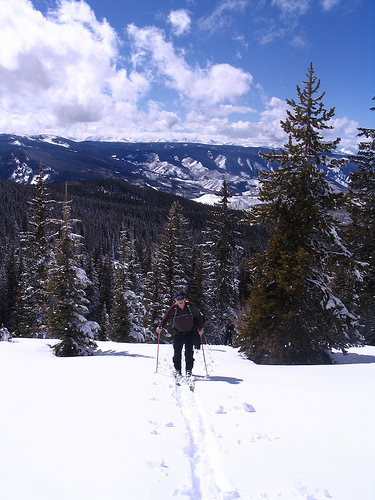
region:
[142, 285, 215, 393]
skier on snowy hill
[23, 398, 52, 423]
white snow on the ground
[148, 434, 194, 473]
white snow on the ground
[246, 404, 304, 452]
white snow on the ground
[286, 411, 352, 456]
white snow on the ground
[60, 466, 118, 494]
white snow on the ground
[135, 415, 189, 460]
white snow on the ground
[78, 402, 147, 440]
white snow on the ground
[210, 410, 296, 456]
white snow on the ground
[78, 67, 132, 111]
white clouds in blue sky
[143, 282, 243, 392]
person skiing on snow covered hill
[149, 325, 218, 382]
two ski poles in snow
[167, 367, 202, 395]
two skiis on person's feet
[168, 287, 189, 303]
balck hat on skier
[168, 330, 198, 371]
black snow pants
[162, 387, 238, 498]
ski trail in snow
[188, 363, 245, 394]
balck shadow of skier on white snow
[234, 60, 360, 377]
tall tree in snow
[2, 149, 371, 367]
many tall evergreen trees in snow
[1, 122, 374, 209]
mountains in horizon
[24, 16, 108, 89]
white clouds in blue sky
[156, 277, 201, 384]
skier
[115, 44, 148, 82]
white clouds in blue sky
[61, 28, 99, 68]
white clouds in blue sky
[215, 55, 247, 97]
white clouds in blue sky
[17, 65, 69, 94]
white clouds in blue sky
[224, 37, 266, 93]
white clouds in blue sky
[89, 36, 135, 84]
white clouds in blue sky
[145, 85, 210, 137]
white clouds in blue sky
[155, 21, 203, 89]
white clouds in blue sky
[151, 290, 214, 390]
a man with ski gear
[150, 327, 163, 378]
a red and black ski pole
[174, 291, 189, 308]
a man in shades and a hat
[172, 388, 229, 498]
a packed down ski path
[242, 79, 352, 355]
a tall green tree covered in snow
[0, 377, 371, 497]
a long snowy path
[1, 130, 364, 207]
a distant range of mountains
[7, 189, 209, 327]
an endless snowy forest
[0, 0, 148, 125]
a cloudy sky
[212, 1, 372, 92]
a clear blue sky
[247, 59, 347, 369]
tall green Christmas tree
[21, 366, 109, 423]
fresh white snow on the ground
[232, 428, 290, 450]
foot prints in the snow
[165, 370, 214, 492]
fresh tracks in the snow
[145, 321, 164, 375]
long pole in man's hand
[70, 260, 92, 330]
white snow on the tree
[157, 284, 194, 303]
blue cap on skier's head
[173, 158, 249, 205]
snow capped mountain range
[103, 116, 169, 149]
soft white cloud at the mountain's peak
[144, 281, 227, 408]
man skiing on snow